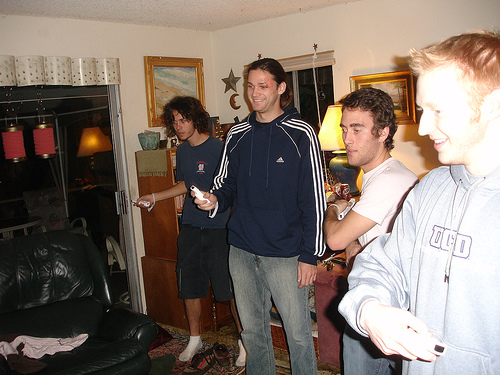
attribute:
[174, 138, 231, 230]
shirt — blue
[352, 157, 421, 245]
t-shirt — white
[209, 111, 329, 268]
hoodie — blue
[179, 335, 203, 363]
sock — white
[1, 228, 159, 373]
chair — leather, black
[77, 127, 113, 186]
lamp — gold, reflective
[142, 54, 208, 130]
frame — gold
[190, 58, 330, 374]
man — standing, playing, smiling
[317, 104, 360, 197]
light — blue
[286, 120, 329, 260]
stripe — white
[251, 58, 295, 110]
hair — long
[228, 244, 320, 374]
jeans — blue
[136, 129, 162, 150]
bowl — blue